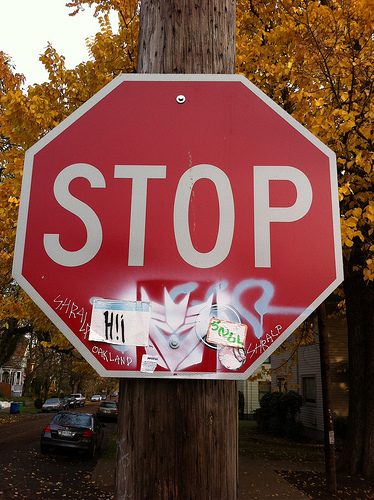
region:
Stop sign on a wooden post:
[6, 42, 373, 409]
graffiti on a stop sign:
[57, 294, 291, 374]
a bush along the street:
[6, 388, 25, 426]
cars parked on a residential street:
[47, 384, 123, 476]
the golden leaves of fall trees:
[343, 149, 372, 265]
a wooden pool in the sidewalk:
[316, 316, 354, 488]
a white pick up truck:
[70, 383, 89, 413]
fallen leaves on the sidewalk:
[250, 423, 328, 498]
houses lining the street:
[9, 333, 96, 408]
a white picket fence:
[4, 398, 15, 410]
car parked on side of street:
[37, 407, 101, 460]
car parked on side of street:
[98, 401, 118, 419]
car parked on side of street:
[41, 395, 59, 412]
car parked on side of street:
[67, 392, 85, 404]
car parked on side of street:
[91, 393, 100, 401]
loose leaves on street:
[30, 461, 85, 497]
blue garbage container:
[9, 395, 27, 415]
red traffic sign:
[26, 88, 345, 379]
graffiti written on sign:
[246, 317, 291, 359]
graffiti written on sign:
[52, 290, 88, 338]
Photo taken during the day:
[14, 0, 365, 496]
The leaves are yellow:
[1, 41, 364, 239]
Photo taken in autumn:
[0, 3, 369, 496]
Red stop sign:
[9, 66, 350, 389]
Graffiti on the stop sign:
[84, 275, 308, 379]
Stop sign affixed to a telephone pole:
[26, 8, 344, 403]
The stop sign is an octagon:
[11, 64, 354, 392]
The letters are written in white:
[41, 159, 312, 270]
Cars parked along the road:
[36, 390, 115, 460]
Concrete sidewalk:
[239, 453, 306, 493]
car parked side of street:
[37, 403, 101, 471]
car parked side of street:
[96, 397, 118, 417]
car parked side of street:
[43, 397, 62, 409]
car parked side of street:
[65, 395, 76, 403]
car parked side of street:
[91, 391, 102, 402]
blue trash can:
[8, 399, 25, 418]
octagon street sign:
[28, 70, 330, 380]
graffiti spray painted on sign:
[152, 274, 278, 318]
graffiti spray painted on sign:
[240, 322, 286, 363]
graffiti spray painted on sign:
[85, 342, 137, 373]